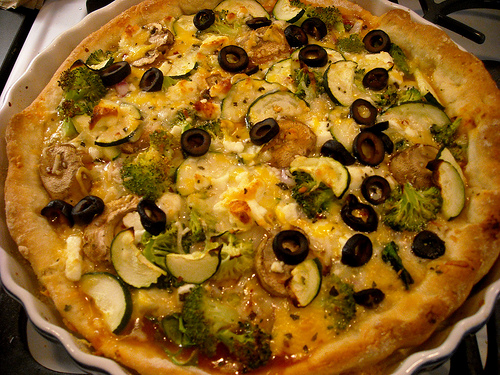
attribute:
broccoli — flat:
[380, 178, 444, 233]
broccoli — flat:
[172, 281, 259, 353]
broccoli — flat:
[115, 132, 180, 199]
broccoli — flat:
[52, 63, 110, 120]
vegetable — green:
[387, 184, 442, 232]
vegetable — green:
[180, 289, 240, 358]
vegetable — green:
[124, 162, 159, 195]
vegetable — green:
[325, 273, 355, 333]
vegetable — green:
[58, 66, 105, 114]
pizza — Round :
[4, 2, 496, 371]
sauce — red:
[131, 308, 300, 373]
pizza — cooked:
[18, 6, 433, 371]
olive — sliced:
[259, 126, 292, 146]